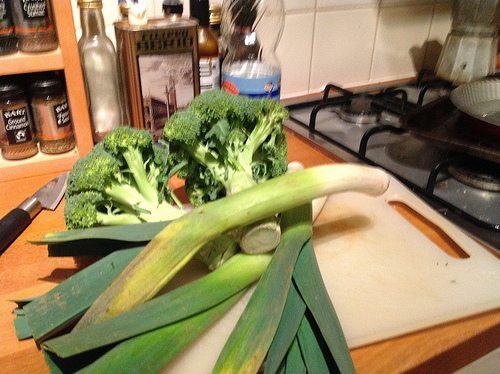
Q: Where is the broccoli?
A: On a cutting board.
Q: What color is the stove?
A: Black.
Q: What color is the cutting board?
A: White.